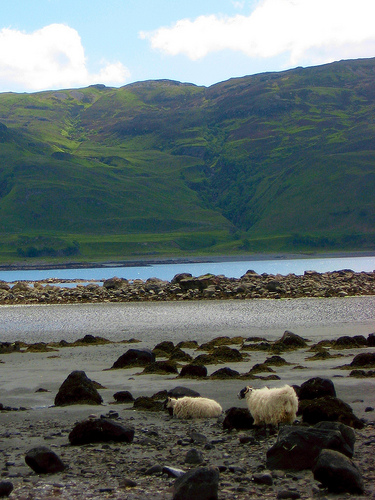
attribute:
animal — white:
[240, 379, 306, 424]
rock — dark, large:
[53, 375, 97, 406]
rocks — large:
[49, 366, 358, 485]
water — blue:
[190, 254, 349, 277]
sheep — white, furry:
[168, 363, 301, 440]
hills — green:
[29, 129, 340, 259]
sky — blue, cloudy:
[17, 11, 311, 67]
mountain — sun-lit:
[21, 89, 349, 225]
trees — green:
[27, 225, 357, 257]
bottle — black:
[154, 459, 192, 480]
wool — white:
[253, 396, 292, 425]